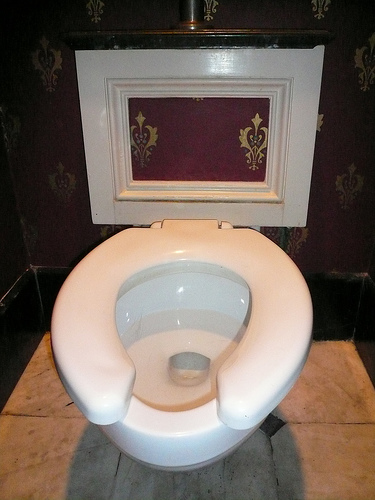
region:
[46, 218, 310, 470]
white toilet bowl with seat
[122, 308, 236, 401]
water in toilet bowl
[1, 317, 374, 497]
biege tiles on floor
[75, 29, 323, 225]
decorated tank of toilet bowl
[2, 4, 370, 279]
wallpaper on back wall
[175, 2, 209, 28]
metal pipe connected to the toilet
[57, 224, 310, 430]
white toilet seat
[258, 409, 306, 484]
damage on the tile floor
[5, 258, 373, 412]
black baseboard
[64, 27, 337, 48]
black lid of toilet tank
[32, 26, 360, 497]
a white bathroom toilet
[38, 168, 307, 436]
a white toilet with white seat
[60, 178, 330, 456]
a clean white toilet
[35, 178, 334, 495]
a clean bathroom toilet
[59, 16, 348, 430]
a toilet with white frame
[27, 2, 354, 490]
a toilet on the wall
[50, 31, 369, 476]
a toilet inside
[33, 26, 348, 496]
a white toilet inside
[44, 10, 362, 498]
a toilet in a bathroom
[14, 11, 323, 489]
a white toilet in the bathroom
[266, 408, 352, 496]
white cracked tile on the bathroom floor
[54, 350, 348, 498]
shadow of the toilet on the ground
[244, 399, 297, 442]
black spot on the white tile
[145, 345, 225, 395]
hole in the toilet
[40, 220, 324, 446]
white toilet seat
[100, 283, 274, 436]
water filled in the toilet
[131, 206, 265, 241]
hinges of the toilet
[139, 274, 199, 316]
light reflecting on the toilet bowl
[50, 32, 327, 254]
white frame on the wall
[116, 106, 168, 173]
golden design on the red wall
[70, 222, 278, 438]
A very clean white toilet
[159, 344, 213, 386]
Water in the toilet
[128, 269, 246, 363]
The inside of the toilet bowl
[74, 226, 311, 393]
A white toilet seat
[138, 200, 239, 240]
The hinge of the toilet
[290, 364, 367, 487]
Stone tile on the floor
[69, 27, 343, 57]
A black toilet tank cover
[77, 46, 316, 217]
A toilet tank with an intricate design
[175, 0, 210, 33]
A metal tube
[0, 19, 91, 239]
Red and gold wallpaper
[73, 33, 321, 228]
A picture frame-like back to the toilet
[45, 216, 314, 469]
A clean white porcelain toilet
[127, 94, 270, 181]
Wallpaper in the middle of the toilet frame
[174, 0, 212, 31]
A metal pole likely leading to the flushing device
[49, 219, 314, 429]
A curved white toilet seat with no lid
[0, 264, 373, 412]
Dusty black baseboards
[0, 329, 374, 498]
A dirty tiled floor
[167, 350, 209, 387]
A clean, water-filled toilet drain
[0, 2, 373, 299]
Dark red wallpaper with a decorative golden design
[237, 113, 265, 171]
A decorative gold and brown design on the wallpaper